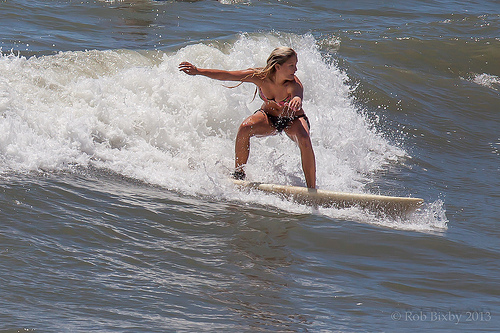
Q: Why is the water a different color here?
A: The sun is reflecting off of it.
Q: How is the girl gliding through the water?
A: She is riding a surfboard.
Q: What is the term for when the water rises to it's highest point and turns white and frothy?
A: A breaker.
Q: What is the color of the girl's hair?
A: Blonde.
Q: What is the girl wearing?
A: A bikini.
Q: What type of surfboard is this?
A: A short board.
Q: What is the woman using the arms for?
A: Balance.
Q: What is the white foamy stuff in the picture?
A: Wave.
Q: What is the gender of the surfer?
A: Female.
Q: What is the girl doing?
A: Surfing.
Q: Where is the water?
A: Ocean.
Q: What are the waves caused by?
A: Water.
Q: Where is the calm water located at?
A: Ocean.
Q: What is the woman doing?
A: Surfing.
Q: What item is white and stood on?
A: Surfboard.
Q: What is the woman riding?
A: Wave.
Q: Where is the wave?
A: Behind the woman.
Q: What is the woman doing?
A: Surfing.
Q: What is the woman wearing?
A: A bikini.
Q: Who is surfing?
A: The young woman.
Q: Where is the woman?
A: On the surfboard.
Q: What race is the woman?
A: White.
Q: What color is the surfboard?
A: White.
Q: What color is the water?
A: Blue.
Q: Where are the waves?
A: In water.